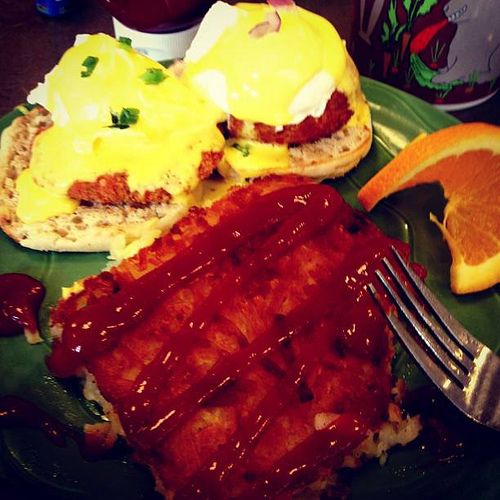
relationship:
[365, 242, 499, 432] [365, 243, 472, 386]
fork has prongs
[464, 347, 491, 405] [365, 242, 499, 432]
light shining on fork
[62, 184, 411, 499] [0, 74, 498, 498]
hash browns sitting on plate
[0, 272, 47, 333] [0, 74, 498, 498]
ketchup squeezed onto plate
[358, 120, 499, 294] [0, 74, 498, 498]
orange sitting on plate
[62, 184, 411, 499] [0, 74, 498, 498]
hash browns on plate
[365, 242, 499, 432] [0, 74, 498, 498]
fork above plate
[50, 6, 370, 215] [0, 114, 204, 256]
sauce on biscuit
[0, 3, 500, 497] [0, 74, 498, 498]
food on plate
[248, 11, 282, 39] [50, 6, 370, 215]
mushroom stuck in sauce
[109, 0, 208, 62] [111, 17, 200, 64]
bottle has lid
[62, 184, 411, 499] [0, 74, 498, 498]
hash browns resting on plate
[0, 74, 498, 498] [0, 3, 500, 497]
plate below food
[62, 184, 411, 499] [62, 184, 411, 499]
ketchup drizzled over hash browns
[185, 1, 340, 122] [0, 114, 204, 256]
egg cracked onto biscuit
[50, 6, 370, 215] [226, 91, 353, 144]
sauce on top of patty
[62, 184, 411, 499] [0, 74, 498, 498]
hash browns served on plate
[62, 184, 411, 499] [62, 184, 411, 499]
ketchup on top of hash browns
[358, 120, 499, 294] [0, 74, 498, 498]
orange resting on plate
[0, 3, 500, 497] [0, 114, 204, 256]
food on top of biscuit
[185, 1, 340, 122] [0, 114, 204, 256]
egg covering biscuit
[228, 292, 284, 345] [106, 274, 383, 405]
bbq sauce on ribs